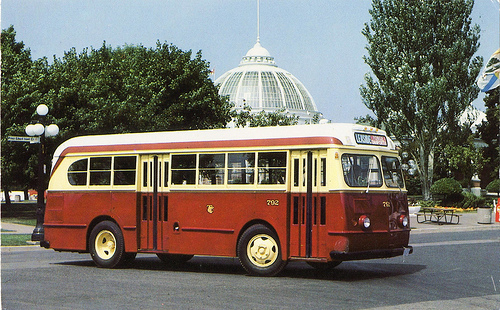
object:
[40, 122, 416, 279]
bus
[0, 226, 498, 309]
street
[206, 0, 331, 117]
dome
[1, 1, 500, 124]
background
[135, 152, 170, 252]
door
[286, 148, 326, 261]
door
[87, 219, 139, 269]
tire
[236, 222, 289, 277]
front tire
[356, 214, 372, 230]
headlights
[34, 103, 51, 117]
lamp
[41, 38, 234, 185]
tree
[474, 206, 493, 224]
garbage can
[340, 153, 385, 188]
window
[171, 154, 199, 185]
window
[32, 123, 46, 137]
lights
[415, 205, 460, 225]
picnic table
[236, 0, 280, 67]
top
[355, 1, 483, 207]
tree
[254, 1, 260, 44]
rod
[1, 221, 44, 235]
walkway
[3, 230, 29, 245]
grass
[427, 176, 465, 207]
bush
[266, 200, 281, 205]
number